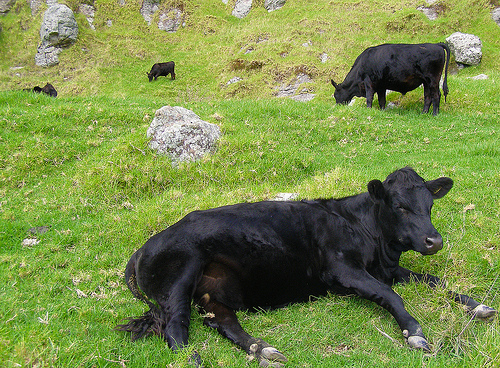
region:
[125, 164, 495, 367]
a black cow resting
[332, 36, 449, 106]
a black cow grazing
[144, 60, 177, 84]
a black cow grazing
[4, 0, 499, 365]
a green grassy field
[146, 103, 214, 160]
a large grey rock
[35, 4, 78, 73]
a large grey rock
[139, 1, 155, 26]
a large grey rock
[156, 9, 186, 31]
a large grey rock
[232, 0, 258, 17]
a large grey rock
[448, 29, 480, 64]
a large grey rock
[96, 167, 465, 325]
black cow in a field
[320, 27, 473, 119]
black cow in a field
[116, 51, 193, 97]
black cow in a field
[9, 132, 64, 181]
short green and yellow grass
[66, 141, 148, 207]
short green and yellow grass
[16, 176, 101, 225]
short green and yellow grass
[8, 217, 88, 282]
short green and yellow grass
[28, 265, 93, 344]
short green and yellow grass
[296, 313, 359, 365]
short green and yellow grass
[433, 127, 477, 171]
short green and yellow grass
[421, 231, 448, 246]
black nose on front cow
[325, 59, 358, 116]
grazing cow pointing left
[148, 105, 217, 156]
white large rock in field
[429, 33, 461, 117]
black tail on grazing cow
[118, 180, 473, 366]
black cow lying down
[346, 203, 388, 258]
black wrinkles lower neck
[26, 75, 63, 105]
partial black portion of cow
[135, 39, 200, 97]
cow grazing further in the picture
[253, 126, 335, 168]
bright green grass in center of picture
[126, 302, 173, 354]
black tail of cow lying down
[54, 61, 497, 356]
a cow laying down on the ground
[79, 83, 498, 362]
a black cow laying on the ground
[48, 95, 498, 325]
a black cow laying on grass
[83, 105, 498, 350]
a cow laying on the grass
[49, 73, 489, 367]
a black cow laying in a field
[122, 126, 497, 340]
a cow laying in a green field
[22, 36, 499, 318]
a field of cows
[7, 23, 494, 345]
a field of black cows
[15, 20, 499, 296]
a field of cows standing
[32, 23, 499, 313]
a field of cows standing and laying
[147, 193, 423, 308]
The cow is laying in the grass.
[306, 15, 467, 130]
The cow is eating grass.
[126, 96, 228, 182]
A big rock in the grass.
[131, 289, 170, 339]
The cow tail on the ground.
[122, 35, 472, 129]
Cows in the field.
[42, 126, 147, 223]
The grass is green.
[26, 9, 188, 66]
Big rocks in the field.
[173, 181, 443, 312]
The cow is black.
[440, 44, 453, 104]
The cow tail is long and black.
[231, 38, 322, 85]
Patches of grass on the ground.